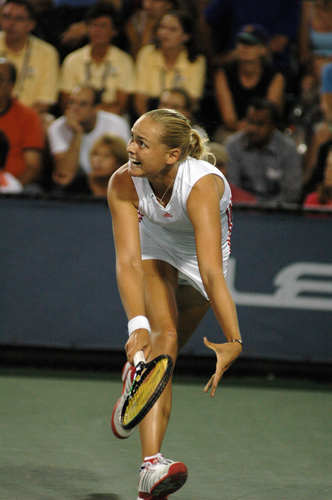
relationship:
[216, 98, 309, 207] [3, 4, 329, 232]
spectator in stands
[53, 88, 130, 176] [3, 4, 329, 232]
spectator in stands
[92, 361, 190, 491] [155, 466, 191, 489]
shoes have red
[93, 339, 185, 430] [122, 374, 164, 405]
racket has yellow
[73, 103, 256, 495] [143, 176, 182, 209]
woman has necklace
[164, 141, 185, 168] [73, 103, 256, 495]
ear of woman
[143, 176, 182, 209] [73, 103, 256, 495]
necklace on woman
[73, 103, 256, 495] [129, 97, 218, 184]
woman has hair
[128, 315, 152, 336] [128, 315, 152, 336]
band has band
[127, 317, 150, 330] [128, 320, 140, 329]
band has white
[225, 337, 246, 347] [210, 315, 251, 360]
watch on wrist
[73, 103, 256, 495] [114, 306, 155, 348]
woman has wrist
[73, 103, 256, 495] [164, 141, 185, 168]
woman has ear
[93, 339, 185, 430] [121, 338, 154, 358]
racket in hand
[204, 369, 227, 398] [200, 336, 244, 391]
fingers on hand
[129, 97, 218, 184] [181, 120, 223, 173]
hair in ponytail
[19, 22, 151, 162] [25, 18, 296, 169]
spectators in audience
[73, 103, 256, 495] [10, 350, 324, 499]
woman on court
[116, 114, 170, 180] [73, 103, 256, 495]
face of woman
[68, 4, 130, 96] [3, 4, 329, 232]
fan in stands